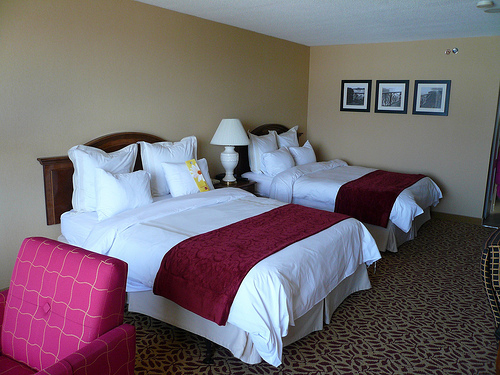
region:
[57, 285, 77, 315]
the couch is pink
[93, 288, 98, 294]
the couch is pink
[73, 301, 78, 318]
the couch is pink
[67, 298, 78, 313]
the couch is pink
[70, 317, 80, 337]
the couch is pink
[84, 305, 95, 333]
the couch is pink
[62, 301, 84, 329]
the couch is pink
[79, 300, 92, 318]
the couch is pink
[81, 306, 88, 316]
the couch is pink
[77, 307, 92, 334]
the couch is pink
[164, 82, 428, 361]
the beds are visible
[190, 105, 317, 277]
the beds are visible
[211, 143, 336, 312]
the beds are visible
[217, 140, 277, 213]
the beds are visible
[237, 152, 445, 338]
the beds are visible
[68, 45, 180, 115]
The wall is tan.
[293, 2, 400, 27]
The ceiling is white.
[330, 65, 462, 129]
Three pictures are on the wall.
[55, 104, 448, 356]
Two beds.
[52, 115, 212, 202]
Four pillows are on the bed.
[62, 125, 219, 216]
The pillows are white.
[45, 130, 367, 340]
The bed is white.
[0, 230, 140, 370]
The chair is red.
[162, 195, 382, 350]
A red sheet is on the bed.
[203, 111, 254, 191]
The lamp is white.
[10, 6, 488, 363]
hotel room with two double beds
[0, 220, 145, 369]
fuchsia and yellow geometric patterned chair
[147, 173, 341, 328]
red blanket on a white bedspread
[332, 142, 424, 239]
red blanket on a white bedspread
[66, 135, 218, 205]
four white pillows on a bed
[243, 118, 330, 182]
four white pillows on a bed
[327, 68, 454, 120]
three black and white photos hanging on a wall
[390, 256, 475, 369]
brown and tan geometric carpet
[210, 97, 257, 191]
white lamp with a white lampshade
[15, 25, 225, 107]
tan hotel wall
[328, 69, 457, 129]
picture frames hung on wall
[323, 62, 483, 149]
picture frames are black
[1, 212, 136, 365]
the chair is red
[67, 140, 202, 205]
the pillows are white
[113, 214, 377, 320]
the comforter is white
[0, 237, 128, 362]
white lines on the chair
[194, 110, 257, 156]
lamp shade is white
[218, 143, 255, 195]
the lamp is white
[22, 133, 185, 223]
the headboard is brown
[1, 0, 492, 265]
the wall is brown